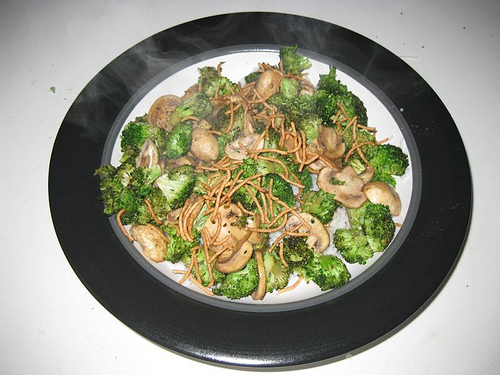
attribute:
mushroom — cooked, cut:
[110, 215, 176, 260]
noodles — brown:
[181, 244, 223, 290]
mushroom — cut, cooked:
[184, 124, 221, 159]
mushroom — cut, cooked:
[201, 202, 258, 272]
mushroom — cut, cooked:
[362, 180, 404, 217]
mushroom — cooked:
[279, 202, 332, 255]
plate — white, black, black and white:
[44, 10, 476, 368]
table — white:
[0, 0, 500, 374]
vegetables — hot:
[174, 83, 383, 231]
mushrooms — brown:
[301, 125, 357, 195]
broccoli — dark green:
[242, 154, 338, 222]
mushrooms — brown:
[275, 199, 345, 266]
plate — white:
[125, 91, 387, 279]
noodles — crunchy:
[201, 138, 301, 224]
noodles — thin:
[212, 93, 322, 165]